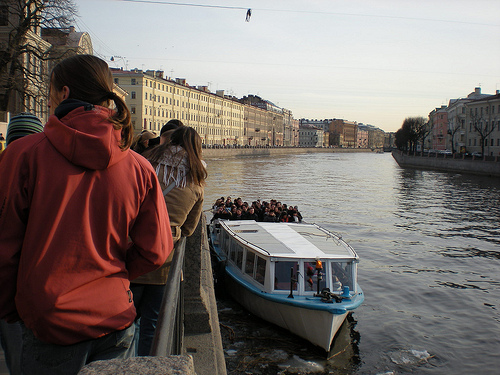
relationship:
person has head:
[5, 36, 182, 366] [43, 46, 128, 146]